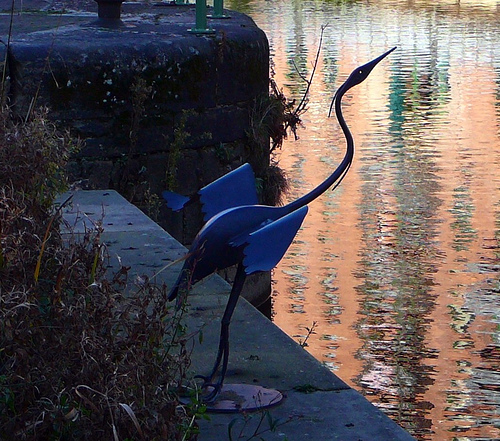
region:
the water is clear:
[388, 172, 492, 280]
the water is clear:
[347, 156, 435, 254]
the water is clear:
[390, 286, 492, 414]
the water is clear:
[294, 16, 396, 136]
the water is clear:
[298, 226, 395, 333]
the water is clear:
[384, 296, 485, 410]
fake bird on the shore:
[157, 45, 439, 437]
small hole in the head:
[353, 65, 368, 75]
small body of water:
[140, 0, 497, 440]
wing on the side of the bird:
[231, 202, 323, 270]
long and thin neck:
[296, 80, 377, 203]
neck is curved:
[303, 88, 370, 198]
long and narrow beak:
[372, 45, 404, 60]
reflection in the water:
[381, 50, 411, 137]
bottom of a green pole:
[187, 0, 217, 37]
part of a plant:
[81, 375, 108, 416]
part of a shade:
[386, 289, 408, 331]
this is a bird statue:
[187, 22, 409, 403]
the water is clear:
[332, 252, 403, 340]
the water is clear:
[278, 221, 409, 331]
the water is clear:
[370, 315, 455, 416]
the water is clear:
[375, 158, 437, 283]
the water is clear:
[361, 323, 448, 398]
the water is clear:
[355, 151, 446, 256]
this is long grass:
[101, 298, 185, 410]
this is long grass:
[52, 273, 132, 378]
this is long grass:
[15, 175, 90, 343]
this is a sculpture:
[33, 23, 480, 368]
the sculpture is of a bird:
[202, 101, 462, 340]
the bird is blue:
[169, 141, 357, 305]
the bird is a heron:
[179, 145, 421, 327]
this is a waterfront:
[112, 195, 492, 358]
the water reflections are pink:
[349, 133, 497, 396]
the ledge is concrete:
[125, 269, 337, 433]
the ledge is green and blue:
[102, 211, 225, 316]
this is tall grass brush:
[75, 280, 200, 435]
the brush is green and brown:
[2, 266, 229, 425]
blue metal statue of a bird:
[160, 43, 397, 414]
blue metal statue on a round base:
[162, 44, 401, 416]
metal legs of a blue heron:
[199, 259, 248, 396]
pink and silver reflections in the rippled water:
[224, 0, 499, 431]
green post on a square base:
[181, 0, 216, 32]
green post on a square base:
[207, 0, 229, 20]